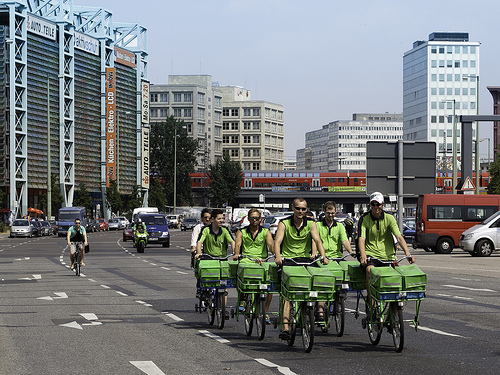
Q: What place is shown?
A: It is a street.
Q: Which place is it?
A: It is a street.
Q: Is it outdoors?
A: Yes, it is outdoors.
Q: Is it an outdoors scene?
A: Yes, it is outdoors.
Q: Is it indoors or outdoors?
A: It is outdoors.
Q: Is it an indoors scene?
A: No, it is outdoors.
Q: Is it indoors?
A: No, it is outdoors.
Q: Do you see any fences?
A: No, there are no fences.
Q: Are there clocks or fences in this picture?
A: No, there are no fences or clocks.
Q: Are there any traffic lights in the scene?
A: No, there are no traffic lights.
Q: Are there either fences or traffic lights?
A: No, there are no traffic lights or fences.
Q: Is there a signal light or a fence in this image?
A: No, there are no traffic lights or fences.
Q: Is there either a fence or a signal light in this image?
A: No, there are no traffic lights or fences.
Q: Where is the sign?
A: The sign is on the street.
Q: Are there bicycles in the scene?
A: Yes, there is a bicycle.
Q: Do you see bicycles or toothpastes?
A: Yes, there is a bicycle.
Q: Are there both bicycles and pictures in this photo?
A: No, there is a bicycle but no pictures.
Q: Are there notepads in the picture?
A: No, there are no notepads.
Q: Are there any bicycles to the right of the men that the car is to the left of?
A: Yes, there is a bicycle to the right of the men.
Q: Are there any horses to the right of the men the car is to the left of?
A: No, there is a bicycle to the right of the men.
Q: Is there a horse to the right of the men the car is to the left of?
A: No, there is a bicycle to the right of the men.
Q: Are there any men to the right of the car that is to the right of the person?
A: Yes, there are men to the right of the car.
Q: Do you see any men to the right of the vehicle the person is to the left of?
A: Yes, there are men to the right of the car.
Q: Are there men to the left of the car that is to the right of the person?
A: No, the men are to the right of the car.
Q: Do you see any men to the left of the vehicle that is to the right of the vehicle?
A: No, the men are to the right of the car.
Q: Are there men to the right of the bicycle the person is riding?
A: Yes, there are men to the right of the bicycle.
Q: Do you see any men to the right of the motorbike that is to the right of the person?
A: Yes, there are men to the right of the motorbike.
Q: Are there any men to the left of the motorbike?
A: No, the men are to the right of the motorbike.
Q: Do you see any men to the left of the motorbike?
A: No, the men are to the right of the motorbike.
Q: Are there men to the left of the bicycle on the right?
A: Yes, there are men to the left of the bicycle.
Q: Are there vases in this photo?
A: No, there are no vases.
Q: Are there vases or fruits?
A: No, there are no vases or fruits.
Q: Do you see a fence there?
A: No, there are no fences.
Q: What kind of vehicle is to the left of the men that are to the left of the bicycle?
A: The vehicle is a car.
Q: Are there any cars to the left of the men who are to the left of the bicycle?
A: Yes, there is a car to the left of the men.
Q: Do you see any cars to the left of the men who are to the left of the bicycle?
A: Yes, there is a car to the left of the men.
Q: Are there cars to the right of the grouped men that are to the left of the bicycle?
A: No, the car is to the left of the men.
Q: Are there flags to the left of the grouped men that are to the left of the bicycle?
A: No, there is a car to the left of the men.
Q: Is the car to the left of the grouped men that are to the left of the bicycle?
A: Yes, the car is to the left of the men.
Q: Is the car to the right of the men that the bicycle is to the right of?
A: No, the car is to the left of the men.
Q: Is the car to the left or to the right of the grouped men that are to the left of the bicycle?
A: The car is to the left of the men.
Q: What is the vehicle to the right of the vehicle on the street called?
A: The vehicle is a car.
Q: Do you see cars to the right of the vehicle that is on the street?
A: Yes, there is a car to the right of the vehicle.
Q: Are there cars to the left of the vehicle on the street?
A: No, the car is to the right of the vehicle.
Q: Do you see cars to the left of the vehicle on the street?
A: No, the car is to the right of the vehicle.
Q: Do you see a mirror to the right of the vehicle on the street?
A: No, there is a car to the right of the vehicle.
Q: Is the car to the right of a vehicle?
A: Yes, the car is to the right of a vehicle.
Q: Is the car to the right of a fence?
A: No, the car is to the right of a vehicle.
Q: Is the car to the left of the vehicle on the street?
A: No, the car is to the right of the vehicle.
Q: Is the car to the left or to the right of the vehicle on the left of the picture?
A: The car is to the right of the vehicle.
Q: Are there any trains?
A: Yes, there is a train.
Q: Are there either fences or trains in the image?
A: Yes, there is a train.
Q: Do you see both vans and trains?
A: Yes, there are both a train and a van.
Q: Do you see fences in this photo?
A: No, there are no fences.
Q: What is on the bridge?
A: The train is on the bridge.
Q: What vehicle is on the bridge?
A: The vehicle is a train.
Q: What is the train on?
A: The train is on the bridge.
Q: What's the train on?
A: The train is on the bridge.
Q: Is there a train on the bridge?
A: Yes, there is a train on the bridge.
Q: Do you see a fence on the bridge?
A: No, there is a train on the bridge.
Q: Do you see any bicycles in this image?
A: Yes, there is a bicycle.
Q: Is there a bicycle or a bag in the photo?
A: Yes, there is a bicycle.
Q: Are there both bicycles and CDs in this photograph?
A: No, there is a bicycle but no cds.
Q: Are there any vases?
A: No, there are no vases.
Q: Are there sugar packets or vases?
A: No, there are no vases or sugar packets.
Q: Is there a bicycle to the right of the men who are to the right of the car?
A: Yes, there is a bicycle to the right of the men.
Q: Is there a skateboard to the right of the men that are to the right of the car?
A: No, there is a bicycle to the right of the men.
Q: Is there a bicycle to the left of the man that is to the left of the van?
A: Yes, there is a bicycle to the left of the man.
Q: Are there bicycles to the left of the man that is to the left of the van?
A: Yes, there is a bicycle to the left of the man.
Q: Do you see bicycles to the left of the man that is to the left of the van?
A: Yes, there is a bicycle to the left of the man.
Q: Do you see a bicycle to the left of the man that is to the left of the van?
A: Yes, there is a bicycle to the left of the man.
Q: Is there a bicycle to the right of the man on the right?
A: No, the bicycle is to the left of the man.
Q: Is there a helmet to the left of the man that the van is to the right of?
A: No, there is a bicycle to the left of the man.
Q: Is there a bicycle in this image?
A: Yes, there is a bicycle.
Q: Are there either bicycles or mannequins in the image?
A: Yes, there is a bicycle.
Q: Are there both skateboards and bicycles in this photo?
A: No, there is a bicycle but no skateboards.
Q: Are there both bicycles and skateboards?
A: No, there is a bicycle but no skateboards.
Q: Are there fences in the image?
A: No, there are no fences.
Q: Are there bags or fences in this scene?
A: No, there are no fences or bags.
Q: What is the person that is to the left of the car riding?
A: The person is riding the bicycle.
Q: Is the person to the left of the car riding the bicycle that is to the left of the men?
A: Yes, the person is riding the bicycle.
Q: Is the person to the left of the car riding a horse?
A: No, the person is riding the bicycle.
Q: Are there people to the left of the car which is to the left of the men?
A: Yes, there is a person to the left of the car.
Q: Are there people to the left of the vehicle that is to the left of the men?
A: Yes, there is a person to the left of the car.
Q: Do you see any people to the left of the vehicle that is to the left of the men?
A: Yes, there is a person to the left of the car.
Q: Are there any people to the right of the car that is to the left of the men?
A: No, the person is to the left of the car.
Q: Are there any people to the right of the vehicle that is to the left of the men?
A: No, the person is to the left of the car.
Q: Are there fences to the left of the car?
A: No, there is a person to the left of the car.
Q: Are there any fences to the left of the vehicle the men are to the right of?
A: No, there is a person to the left of the car.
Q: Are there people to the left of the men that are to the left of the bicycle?
A: Yes, there is a person to the left of the men.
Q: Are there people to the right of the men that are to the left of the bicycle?
A: No, the person is to the left of the men.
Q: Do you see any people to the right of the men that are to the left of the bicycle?
A: No, the person is to the left of the men.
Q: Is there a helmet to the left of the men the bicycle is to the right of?
A: No, there is a person to the left of the men.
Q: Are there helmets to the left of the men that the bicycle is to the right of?
A: No, there is a person to the left of the men.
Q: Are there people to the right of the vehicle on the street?
A: Yes, there is a person to the right of the vehicle.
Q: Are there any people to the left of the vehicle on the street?
A: No, the person is to the right of the vehicle.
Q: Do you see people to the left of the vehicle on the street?
A: No, the person is to the right of the vehicle.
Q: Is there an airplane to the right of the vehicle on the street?
A: No, there is a person to the right of the vehicle.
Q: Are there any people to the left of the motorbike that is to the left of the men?
A: Yes, there is a person to the left of the motorcycle.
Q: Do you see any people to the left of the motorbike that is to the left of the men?
A: Yes, there is a person to the left of the motorcycle.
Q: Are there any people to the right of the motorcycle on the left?
A: No, the person is to the left of the motorbike.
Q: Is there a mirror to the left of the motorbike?
A: No, there is a person to the left of the motorbike.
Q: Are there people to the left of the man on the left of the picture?
A: Yes, there is a person to the left of the man.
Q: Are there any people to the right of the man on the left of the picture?
A: No, the person is to the left of the man.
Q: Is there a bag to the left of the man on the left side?
A: No, there is a person to the left of the man.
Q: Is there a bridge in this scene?
A: Yes, there is a bridge.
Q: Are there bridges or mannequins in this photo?
A: Yes, there is a bridge.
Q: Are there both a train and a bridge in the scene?
A: Yes, there are both a bridge and a train.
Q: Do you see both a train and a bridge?
A: Yes, there are both a bridge and a train.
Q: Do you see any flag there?
A: No, there are no flags.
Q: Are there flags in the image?
A: No, there are no flags.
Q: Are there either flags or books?
A: No, there are no flags or books.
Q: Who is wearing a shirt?
A: The man is wearing a shirt.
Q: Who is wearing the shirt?
A: The man is wearing a shirt.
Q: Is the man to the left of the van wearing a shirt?
A: Yes, the man is wearing a shirt.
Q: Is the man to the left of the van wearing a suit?
A: No, the man is wearing a shirt.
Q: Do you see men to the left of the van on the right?
A: Yes, there is a man to the left of the van.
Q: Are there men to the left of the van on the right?
A: Yes, there is a man to the left of the van.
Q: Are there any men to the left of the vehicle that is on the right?
A: Yes, there is a man to the left of the van.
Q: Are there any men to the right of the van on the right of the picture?
A: No, the man is to the left of the van.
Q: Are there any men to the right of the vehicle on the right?
A: No, the man is to the left of the van.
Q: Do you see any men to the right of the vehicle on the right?
A: No, the man is to the left of the van.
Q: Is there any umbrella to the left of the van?
A: No, there is a man to the left of the van.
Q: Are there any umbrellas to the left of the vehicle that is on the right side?
A: No, there is a man to the left of the van.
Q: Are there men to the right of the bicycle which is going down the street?
A: Yes, there is a man to the right of the bicycle.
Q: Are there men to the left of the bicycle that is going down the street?
A: No, the man is to the right of the bicycle.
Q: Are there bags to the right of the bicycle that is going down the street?
A: No, there is a man to the right of the bicycle.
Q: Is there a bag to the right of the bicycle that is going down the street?
A: No, there is a man to the right of the bicycle.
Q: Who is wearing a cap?
A: The man is wearing a cap.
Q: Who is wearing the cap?
A: The man is wearing a cap.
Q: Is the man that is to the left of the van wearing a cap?
A: Yes, the man is wearing a cap.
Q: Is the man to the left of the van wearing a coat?
A: No, the man is wearing a cap.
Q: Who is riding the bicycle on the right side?
A: The man is riding the bicycle.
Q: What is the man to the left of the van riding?
A: The man is riding the bicycle.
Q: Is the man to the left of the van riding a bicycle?
A: Yes, the man is riding a bicycle.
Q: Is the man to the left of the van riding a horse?
A: No, the man is riding a bicycle.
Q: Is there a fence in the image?
A: No, there are no fences.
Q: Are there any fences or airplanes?
A: No, there are no fences or airplanes.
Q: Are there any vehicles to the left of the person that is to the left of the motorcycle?
A: Yes, there is a vehicle to the left of the person.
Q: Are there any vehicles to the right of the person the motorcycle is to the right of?
A: No, the vehicle is to the left of the person.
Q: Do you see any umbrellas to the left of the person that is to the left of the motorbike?
A: No, there is a vehicle to the left of the person.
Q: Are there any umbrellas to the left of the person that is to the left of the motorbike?
A: No, there is a vehicle to the left of the person.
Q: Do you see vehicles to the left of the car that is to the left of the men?
A: Yes, there is a vehicle to the left of the car.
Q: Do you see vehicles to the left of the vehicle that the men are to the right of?
A: Yes, there is a vehicle to the left of the car.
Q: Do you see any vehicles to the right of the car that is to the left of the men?
A: No, the vehicle is to the left of the car.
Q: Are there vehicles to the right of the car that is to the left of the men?
A: No, the vehicle is to the left of the car.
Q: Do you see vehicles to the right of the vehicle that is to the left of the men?
A: No, the vehicle is to the left of the car.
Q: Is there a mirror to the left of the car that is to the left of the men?
A: No, there is a vehicle to the left of the car.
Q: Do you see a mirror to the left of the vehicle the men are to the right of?
A: No, there is a vehicle to the left of the car.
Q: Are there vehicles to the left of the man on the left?
A: Yes, there is a vehicle to the left of the man.